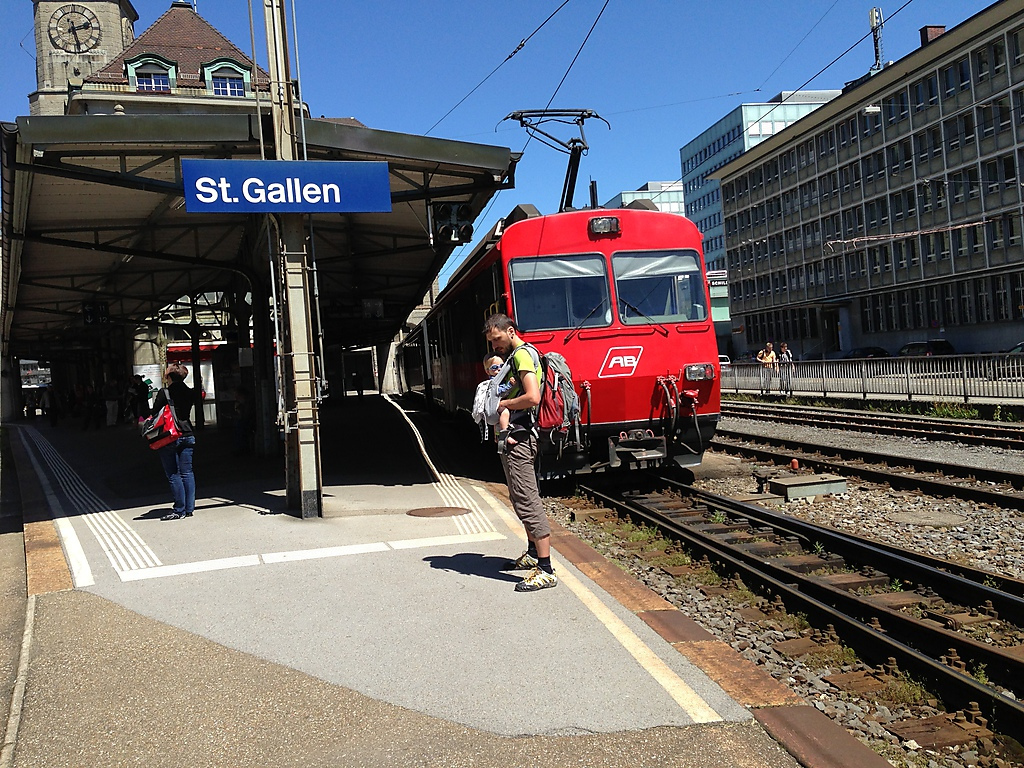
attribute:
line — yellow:
[572, 587, 706, 734]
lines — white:
[186, 528, 409, 574]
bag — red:
[136, 400, 178, 452]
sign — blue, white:
[177, 153, 394, 214]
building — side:
[669, 71, 1021, 329]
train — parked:
[390, 199, 727, 494]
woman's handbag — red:
[134, 380, 192, 460]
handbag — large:
[129, 403, 183, 446]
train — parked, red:
[372, 187, 797, 495]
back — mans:
[503, 345, 596, 426]